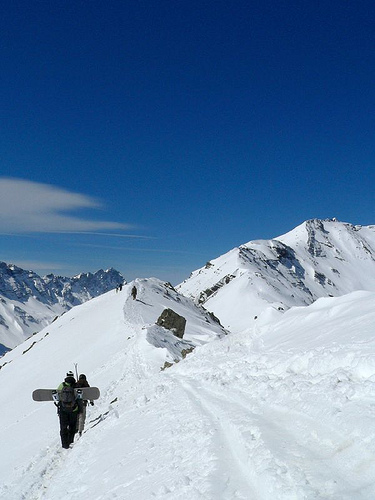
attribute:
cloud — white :
[2, 175, 177, 280]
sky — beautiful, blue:
[2, 2, 373, 263]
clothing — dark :
[119, 283, 122, 289]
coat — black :
[129, 286, 137, 294]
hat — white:
[66, 371, 72, 378]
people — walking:
[50, 363, 98, 453]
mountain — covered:
[6, 212, 374, 498]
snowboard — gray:
[30, 385, 100, 403]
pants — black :
[56, 412, 77, 448]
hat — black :
[63, 374, 83, 391]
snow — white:
[211, 235, 292, 305]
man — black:
[56, 372, 83, 448]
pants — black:
[60, 407, 78, 445]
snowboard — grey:
[30, 387, 101, 401]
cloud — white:
[3, 149, 159, 255]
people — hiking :
[57, 370, 77, 450]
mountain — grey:
[85, 268, 220, 359]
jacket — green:
[56, 374, 88, 412]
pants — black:
[132, 293, 138, 299]